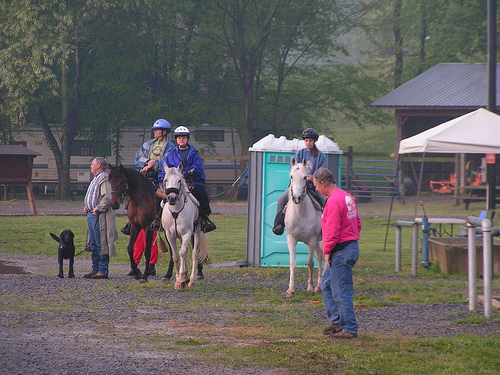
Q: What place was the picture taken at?
A: It was taken at the park.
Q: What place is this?
A: It is a park.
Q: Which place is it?
A: It is a park.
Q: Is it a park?
A: Yes, it is a park.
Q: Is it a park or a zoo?
A: It is a park.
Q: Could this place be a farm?
A: No, it is a park.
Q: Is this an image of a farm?
A: No, the picture is showing a park.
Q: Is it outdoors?
A: Yes, it is outdoors.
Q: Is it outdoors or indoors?
A: It is outdoors.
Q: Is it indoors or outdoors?
A: It is outdoors.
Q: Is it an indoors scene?
A: No, it is outdoors.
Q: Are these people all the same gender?
A: No, they are both male and female.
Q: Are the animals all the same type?
A: No, there are both horses and dogs.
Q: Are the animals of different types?
A: Yes, they are horses and dogs.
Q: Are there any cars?
A: No, there are no cars.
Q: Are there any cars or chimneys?
A: No, there are no cars or chimneys.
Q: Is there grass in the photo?
A: Yes, there is grass.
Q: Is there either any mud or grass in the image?
A: Yes, there is grass.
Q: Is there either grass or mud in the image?
A: Yes, there is grass.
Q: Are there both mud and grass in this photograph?
A: No, there is grass but no mud.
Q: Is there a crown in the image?
A: No, there are no crowns.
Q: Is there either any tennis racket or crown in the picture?
A: No, there are no crowns or rackets.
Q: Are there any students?
A: No, there are no students.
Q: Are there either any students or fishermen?
A: No, there are no students or fishermen.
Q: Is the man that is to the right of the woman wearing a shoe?
A: Yes, the man is wearing a shoe.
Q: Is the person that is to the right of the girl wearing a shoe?
A: Yes, the man is wearing a shoe.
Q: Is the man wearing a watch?
A: No, the man is wearing a shoe.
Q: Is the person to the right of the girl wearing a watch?
A: No, the man is wearing a shoe.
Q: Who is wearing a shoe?
A: The man is wearing a shoe.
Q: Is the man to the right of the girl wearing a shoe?
A: Yes, the man is wearing a shoe.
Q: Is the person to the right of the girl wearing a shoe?
A: Yes, the man is wearing a shoe.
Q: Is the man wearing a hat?
A: No, the man is wearing a shoe.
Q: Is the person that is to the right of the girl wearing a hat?
A: No, the man is wearing a shoe.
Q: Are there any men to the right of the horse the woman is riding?
A: Yes, there is a man to the right of the horse.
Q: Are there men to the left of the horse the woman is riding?
A: No, the man is to the right of the horse.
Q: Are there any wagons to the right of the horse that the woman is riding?
A: No, there is a man to the right of the horse.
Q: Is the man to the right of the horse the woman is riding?
A: Yes, the man is to the right of the horse.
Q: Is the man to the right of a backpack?
A: No, the man is to the right of the horse.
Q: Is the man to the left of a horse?
A: No, the man is to the right of a horse.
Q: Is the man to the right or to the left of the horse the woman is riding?
A: The man is to the right of the horse.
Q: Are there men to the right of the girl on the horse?
A: Yes, there is a man to the right of the girl.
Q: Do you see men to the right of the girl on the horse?
A: Yes, there is a man to the right of the girl.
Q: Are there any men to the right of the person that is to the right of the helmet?
A: Yes, there is a man to the right of the girl.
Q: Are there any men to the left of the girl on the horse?
A: No, the man is to the right of the girl.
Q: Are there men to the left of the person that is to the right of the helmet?
A: No, the man is to the right of the girl.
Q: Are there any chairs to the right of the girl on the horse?
A: No, there is a man to the right of the girl.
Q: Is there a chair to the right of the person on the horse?
A: No, there is a man to the right of the girl.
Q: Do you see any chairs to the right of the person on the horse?
A: No, there is a man to the right of the girl.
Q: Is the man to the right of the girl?
A: Yes, the man is to the right of the girl.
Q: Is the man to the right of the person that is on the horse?
A: Yes, the man is to the right of the girl.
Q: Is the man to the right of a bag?
A: No, the man is to the right of the girl.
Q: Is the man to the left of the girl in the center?
A: No, the man is to the right of the girl.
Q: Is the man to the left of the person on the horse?
A: No, the man is to the right of the girl.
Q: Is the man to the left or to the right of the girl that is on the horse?
A: The man is to the right of the girl.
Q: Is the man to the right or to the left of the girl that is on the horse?
A: The man is to the right of the girl.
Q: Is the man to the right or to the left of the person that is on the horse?
A: The man is to the right of the girl.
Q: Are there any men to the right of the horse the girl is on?
A: Yes, there is a man to the right of the horse.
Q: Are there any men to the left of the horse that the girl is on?
A: No, the man is to the right of the horse.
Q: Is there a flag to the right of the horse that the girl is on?
A: No, there is a man to the right of the horse.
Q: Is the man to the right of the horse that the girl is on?
A: Yes, the man is to the right of the horse.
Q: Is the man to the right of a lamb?
A: No, the man is to the right of the horse.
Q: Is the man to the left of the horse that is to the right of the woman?
A: No, the man is to the right of the horse.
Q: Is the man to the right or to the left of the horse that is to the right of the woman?
A: The man is to the right of the horse.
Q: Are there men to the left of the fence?
A: Yes, there is a man to the left of the fence.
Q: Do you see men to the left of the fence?
A: Yes, there is a man to the left of the fence.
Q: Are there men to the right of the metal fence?
A: No, the man is to the left of the fence.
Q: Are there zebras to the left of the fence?
A: No, there is a man to the left of the fence.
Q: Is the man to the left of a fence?
A: Yes, the man is to the left of a fence.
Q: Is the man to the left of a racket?
A: No, the man is to the left of a fence.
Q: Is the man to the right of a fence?
A: No, the man is to the left of a fence.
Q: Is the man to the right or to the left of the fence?
A: The man is to the left of the fence.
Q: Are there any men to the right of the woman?
A: Yes, there is a man to the right of the woman.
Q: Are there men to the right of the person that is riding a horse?
A: Yes, there is a man to the right of the woman.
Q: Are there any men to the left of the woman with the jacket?
A: No, the man is to the right of the woman.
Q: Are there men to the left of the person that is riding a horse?
A: No, the man is to the right of the woman.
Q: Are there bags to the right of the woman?
A: No, there is a man to the right of the woman.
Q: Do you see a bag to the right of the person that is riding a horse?
A: No, there is a man to the right of the woman.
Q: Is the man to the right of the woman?
A: Yes, the man is to the right of the woman.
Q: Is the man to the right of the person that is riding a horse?
A: Yes, the man is to the right of the woman.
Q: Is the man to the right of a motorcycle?
A: No, the man is to the right of the woman.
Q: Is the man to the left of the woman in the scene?
A: No, the man is to the right of the woman.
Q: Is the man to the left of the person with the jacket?
A: No, the man is to the right of the woman.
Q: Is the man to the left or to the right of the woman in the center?
A: The man is to the right of the woman.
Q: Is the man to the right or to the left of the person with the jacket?
A: The man is to the right of the woman.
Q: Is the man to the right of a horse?
A: Yes, the man is to the right of a horse.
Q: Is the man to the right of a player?
A: No, the man is to the right of a horse.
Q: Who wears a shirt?
A: The man wears a shirt.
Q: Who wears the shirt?
A: The man wears a shirt.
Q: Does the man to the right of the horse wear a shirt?
A: Yes, the man wears a shirt.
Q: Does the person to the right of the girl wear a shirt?
A: Yes, the man wears a shirt.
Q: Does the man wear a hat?
A: No, the man wears a shirt.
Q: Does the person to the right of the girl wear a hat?
A: No, the man wears a shirt.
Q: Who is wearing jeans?
A: The man is wearing jeans.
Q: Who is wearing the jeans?
A: The man is wearing jeans.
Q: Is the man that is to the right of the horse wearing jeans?
A: Yes, the man is wearing jeans.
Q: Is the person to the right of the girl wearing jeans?
A: Yes, the man is wearing jeans.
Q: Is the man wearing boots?
A: No, the man is wearing jeans.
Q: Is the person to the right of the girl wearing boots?
A: No, the man is wearing jeans.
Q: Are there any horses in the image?
A: Yes, there is a horse.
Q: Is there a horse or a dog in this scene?
A: Yes, there is a horse.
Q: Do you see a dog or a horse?
A: Yes, there is a horse.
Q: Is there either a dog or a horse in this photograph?
A: Yes, there is a horse.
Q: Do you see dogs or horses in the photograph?
A: Yes, there is a horse.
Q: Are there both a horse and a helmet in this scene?
A: Yes, there are both a horse and a helmet.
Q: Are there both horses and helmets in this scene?
A: Yes, there are both a horse and a helmet.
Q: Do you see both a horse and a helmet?
A: Yes, there are both a horse and a helmet.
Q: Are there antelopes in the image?
A: No, there are no antelopes.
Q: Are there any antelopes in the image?
A: No, there are no antelopes.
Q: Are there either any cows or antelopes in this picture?
A: No, there are no antelopes or cows.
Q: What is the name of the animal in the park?
A: The animal is a horse.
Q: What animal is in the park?
A: The animal is a horse.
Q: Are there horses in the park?
A: Yes, there is a horse in the park.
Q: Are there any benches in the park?
A: No, there is a horse in the park.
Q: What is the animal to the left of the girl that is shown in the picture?
A: The animal is a horse.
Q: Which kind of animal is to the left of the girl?
A: The animal is a horse.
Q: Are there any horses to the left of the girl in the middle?
A: Yes, there is a horse to the left of the girl.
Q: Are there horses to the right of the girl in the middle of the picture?
A: No, the horse is to the left of the girl.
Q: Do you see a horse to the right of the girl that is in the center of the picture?
A: No, the horse is to the left of the girl.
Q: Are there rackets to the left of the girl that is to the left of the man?
A: No, there is a horse to the left of the girl.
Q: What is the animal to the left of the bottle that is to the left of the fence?
A: The animal is a horse.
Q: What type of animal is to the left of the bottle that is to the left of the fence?
A: The animal is a horse.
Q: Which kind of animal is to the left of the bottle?
A: The animal is a horse.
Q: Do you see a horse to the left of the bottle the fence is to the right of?
A: Yes, there is a horse to the left of the bottle.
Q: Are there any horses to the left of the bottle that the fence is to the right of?
A: Yes, there is a horse to the left of the bottle.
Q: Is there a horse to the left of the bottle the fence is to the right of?
A: Yes, there is a horse to the left of the bottle.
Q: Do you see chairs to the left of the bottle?
A: No, there is a horse to the left of the bottle.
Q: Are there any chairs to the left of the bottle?
A: No, there is a horse to the left of the bottle.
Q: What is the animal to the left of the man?
A: The animal is a horse.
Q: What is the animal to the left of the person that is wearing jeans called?
A: The animal is a horse.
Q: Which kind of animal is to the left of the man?
A: The animal is a horse.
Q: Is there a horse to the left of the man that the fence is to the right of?
A: Yes, there is a horse to the left of the man.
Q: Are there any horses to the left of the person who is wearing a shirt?
A: Yes, there is a horse to the left of the man.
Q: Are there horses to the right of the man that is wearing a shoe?
A: No, the horse is to the left of the man.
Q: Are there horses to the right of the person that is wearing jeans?
A: No, the horse is to the left of the man.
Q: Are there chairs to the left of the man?
A: No, there is a horse to the left of the man.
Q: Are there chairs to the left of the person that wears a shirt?
A: No, there is a horse to the left of the man.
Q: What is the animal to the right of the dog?
A: The animal is a horse.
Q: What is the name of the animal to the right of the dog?
A: The animal is a horse.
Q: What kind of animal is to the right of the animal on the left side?
A: The animal is a horse.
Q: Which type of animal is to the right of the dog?
A: The animal is a horse.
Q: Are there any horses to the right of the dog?
A: Yes, there is a horse to the right of the dog.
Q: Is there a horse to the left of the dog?
A: No, the horse is to the right of the dog.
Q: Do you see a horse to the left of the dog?
A: No, the horse is to the right of the dog.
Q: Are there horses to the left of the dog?
A: No, the horse is to the right of the dog.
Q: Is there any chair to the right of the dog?
A: No, there is a horse to the right of the dog.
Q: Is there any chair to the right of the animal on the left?
A: No, there is a horse to the right of the dog.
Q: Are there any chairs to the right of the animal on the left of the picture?
A: No, there is a horse to the right of the dog.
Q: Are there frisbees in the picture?
A: No, there are no frisbees.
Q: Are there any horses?
A: Yes, there is a horse.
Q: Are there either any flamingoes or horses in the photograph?
A: Yes, there is a horse.